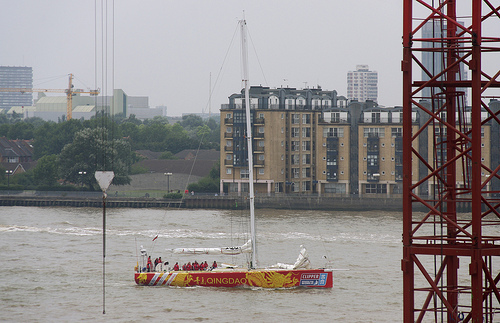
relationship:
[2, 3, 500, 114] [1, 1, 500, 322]
sky in scene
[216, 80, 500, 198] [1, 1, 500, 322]
building in scene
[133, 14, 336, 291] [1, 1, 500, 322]
boat in scene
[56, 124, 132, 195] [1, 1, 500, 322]
tree in scene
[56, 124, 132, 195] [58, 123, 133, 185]
tree has leaves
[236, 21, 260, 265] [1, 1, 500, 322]
pole in scene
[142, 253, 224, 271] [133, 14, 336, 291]
people are on boat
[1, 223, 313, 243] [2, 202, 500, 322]
wake in water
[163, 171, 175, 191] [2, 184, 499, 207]
light on street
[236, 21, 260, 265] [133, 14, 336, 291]
pole attached to boat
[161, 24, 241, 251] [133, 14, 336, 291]
string attached to boat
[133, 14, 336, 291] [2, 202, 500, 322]
boat in water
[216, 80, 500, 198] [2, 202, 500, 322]
building on or side of water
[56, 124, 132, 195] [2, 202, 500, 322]
tree near water